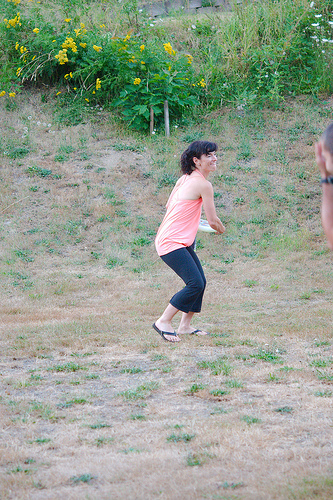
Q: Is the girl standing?
A: Yes, the girl is standing.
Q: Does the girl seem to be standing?
A: Yes, the girl is standing.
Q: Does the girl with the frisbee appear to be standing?
A: Yes, the girl is standing.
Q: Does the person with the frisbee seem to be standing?
A: Yes, the girl is standing.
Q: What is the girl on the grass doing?
A: The girl is standing.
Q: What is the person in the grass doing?
A: The girl is standing.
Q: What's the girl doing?
A: The girl is standing.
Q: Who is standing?
A: The girl is standing.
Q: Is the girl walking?
A: No, the girl is standing.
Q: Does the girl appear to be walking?
A: No, the girl is standing.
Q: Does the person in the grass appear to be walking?
A: No, the girl is standing.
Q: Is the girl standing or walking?
A: The girl is standing.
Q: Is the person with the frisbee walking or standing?
A: The girl is standing.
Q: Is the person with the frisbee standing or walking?
A: The girl is standing.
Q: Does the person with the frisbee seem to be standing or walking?
A: The girl is standing.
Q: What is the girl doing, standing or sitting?
A: The girl is standing.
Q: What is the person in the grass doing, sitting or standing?
A: The girl is standing.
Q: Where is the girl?
A: The girl is on the grass.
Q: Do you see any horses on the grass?
A: No, there is a girl on the grass.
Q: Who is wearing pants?
A: The girl is wearing pants.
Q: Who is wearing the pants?
A: The girl is wearing pants.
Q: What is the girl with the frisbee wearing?
A: The girl is wearing pants.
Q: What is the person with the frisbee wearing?
A: The girl is wearing pants.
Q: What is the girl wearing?
A: The girl is wearing pants.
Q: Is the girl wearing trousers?
A: Yes, the girl is wearing trousers.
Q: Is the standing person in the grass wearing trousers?
A: Yes, the girl is wearing trousers.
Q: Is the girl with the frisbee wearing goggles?
A: No, the girl is wearing trousers.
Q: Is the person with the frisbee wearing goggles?
A: No, the girl is wearing trousers.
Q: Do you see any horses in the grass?
A: No, there is a girl in the grass.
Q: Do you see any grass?
A: Yes, there is grass.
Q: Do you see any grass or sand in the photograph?
A: Yes, there is grass.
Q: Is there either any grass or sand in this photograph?
A: Yes, there is grass.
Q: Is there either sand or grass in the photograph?
A: Yes, there is grass.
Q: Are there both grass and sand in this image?
A: No, there is grass but no sand.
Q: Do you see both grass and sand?
A: No, there is grass but no sand.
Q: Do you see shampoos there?
A: No, there are no shampoos.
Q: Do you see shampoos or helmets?
A: No, there are no shampoos or helmets.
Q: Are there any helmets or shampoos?
A: No, there are no shampoos or helmets.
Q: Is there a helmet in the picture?
A: No, there are no helmets.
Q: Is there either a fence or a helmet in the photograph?
A: No, there are no helmets or fences.